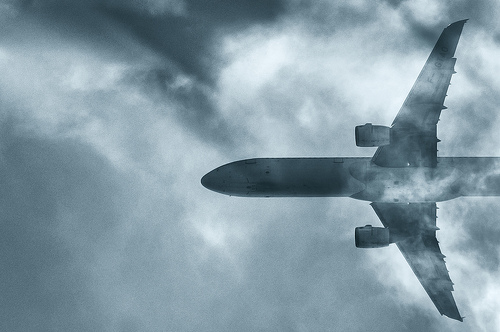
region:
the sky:
[179, 254, 272, 322]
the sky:
[221, 273, 275, 325]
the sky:
[231, 256, 304, 327]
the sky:
[279, 309, 294, 326]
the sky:
[161, 222, 241, 308]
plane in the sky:
[192, 18, 499, 319]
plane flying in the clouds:
[173, 16, 498, 316]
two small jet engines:
[343, 111, 400, 261]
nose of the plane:
[191, 158, 238, 205]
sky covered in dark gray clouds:
[1, 2, 494, 329]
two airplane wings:
[352, 21, 490, 325]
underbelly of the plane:
[301, 158, 479, 200]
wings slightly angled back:
[354, 13, 489, 329]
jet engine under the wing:
[353, 198, 484, 319]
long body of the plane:
[276, 157, 498, 203]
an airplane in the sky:
[182, 9, 475, 289]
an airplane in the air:
[183, 2, 482, 302]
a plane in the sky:
[129, 22, 450, 317]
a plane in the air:
[208, 47, 496, 322]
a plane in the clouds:
[112, 9, 497, 299]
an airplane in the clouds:
[184, 27, 498, 314]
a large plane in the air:
[146, 45, 499, 270]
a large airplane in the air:
[182, 17, 472, 330]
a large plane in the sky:
[178, 17, 498, 317]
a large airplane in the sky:
[134, 0, 479, 331]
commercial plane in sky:
[191, 11, 495, 324]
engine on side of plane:
[338, 210, 400, 258]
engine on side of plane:
[341, 113, 401, 158]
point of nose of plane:
[187, 143, 292, 218]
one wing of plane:
[405, 1, 477, 106]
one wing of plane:
[387, 244, 464, 329]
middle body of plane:
[426, 146, 495, 203]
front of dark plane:
[273, 151, 365, 209]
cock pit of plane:
[239, 153, 269, 188]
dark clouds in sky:
[46, 90, 208, 218]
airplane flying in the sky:
[198, 15, 498, 314]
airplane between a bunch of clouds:
[202, 15, 499, 325]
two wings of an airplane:
[373, 15, 466, 320]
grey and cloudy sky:
[10, 5, 482, 330]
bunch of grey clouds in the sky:
[5, 9, 480, 316]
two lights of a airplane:
[352, 120, 394, 255]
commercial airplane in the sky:
[193, 20, 492, 317]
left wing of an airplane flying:
[383, 17, 463, 166]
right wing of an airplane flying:
[365, 194, 463, 323]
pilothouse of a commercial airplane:
[221, 152, 257, 174]